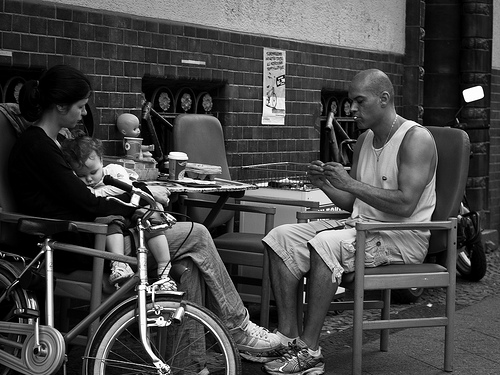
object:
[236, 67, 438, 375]
man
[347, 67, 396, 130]
head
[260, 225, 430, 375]
leg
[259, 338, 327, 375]
tennis shoe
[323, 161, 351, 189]
hand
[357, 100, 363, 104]
eye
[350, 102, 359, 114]
nose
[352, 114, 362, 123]
mouth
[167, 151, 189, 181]
cup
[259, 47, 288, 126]
picture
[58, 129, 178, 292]
baby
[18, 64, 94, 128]
head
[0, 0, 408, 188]
wall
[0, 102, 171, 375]
seat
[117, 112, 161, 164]
babydoll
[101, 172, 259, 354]
table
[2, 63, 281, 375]
woman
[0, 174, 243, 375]
bike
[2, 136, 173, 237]
nest